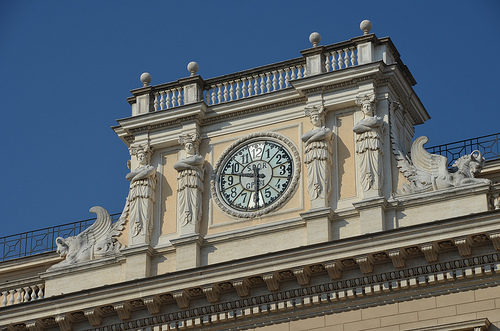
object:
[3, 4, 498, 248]
sky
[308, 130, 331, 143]
arms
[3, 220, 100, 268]
railing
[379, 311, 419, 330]
bricks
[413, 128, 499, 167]
railing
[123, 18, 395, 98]
ledge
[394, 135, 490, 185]
statue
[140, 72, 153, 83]
globes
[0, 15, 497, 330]
wall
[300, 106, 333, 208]
statues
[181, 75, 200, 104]
pillars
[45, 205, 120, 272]
statue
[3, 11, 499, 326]
building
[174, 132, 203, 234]
statues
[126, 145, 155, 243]
statues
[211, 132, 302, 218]
clock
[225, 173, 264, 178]
hands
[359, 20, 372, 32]
globe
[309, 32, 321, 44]
globe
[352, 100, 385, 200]
statue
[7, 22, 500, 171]
clouds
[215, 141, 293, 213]
face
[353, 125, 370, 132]
arms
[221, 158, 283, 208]
9:30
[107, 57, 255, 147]
left side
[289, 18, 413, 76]
right side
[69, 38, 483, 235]
top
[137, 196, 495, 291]
ledge